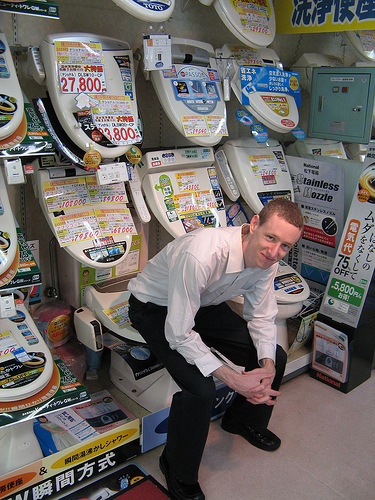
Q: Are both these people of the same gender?
A: No, they are both male and female.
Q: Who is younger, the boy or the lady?
A: The boy is younger than the lady.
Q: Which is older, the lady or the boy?
A: The lady is older than the boy.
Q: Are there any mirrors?
A: No, there are no mirrors.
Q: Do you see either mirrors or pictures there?
A: No, there are no mirrors or pictures.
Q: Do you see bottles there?
A: No, there are no bottles.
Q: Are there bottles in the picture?
A: No, there are no bottles.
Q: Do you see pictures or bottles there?
A: No, there are no bottles or pictures.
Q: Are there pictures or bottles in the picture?
A: No, there are no bottles or pictures.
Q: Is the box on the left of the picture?
A: Yes, the box is on the left of the image.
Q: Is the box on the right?
A: No, the box is on the left of the image.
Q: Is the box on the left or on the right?
A: The box is on the left of the image.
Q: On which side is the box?
A: The box is on the left of the image.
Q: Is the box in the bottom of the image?
A: Yes, the box is in the bottom of the image.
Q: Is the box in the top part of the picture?
A: No, the box is in the bottom of the image.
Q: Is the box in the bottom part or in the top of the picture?
A: The box is in the bottom of the image.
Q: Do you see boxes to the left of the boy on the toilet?
A: Yes, there is a box to the left of the boy.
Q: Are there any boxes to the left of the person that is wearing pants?
A: Yes, there is a box to the left of the boy.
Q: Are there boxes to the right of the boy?
A: No, the box is to the left of the boy.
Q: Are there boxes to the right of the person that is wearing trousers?
A: No, the box is to the left of the boy.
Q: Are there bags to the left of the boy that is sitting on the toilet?
A: No, there is a box to the left of the boy.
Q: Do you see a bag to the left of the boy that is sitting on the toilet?
A: No, there is a box to the left of the boy.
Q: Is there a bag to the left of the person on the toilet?
A: No, there is a box to the left of the boy.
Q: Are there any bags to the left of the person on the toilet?
A: No, there is a box to the left of the boy.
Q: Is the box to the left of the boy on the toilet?
A: Yes, the box is to the left of the boy.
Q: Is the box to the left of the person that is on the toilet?
A: Yes, the box is to the left of the boy.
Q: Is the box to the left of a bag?
A: No, the box is to the left of the boy.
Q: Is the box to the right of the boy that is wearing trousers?
A: No, the box is to the left of the boy.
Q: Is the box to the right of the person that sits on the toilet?
A: No, the box is to the left of the boy.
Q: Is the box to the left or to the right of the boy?
A: The box is to the left of the boy.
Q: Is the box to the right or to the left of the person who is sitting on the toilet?
A: The box is to the left of the boy.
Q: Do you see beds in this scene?
A: No, there are no beds.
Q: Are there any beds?
A: No, there are no beds.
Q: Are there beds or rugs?
A: No, there are no beds or rugs.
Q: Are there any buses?
A: No, there are no buses.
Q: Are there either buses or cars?
A: No, there are no buses or cars.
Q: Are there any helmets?
A: No, there are no helmets.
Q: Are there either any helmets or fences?
A: No, there are no helmets or fences.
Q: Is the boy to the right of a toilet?
A: Yes, the boy is to the right of a toilet.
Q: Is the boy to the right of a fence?
A: No, the boy is to the right of a toilet.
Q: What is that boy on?
A: The boy is on the toilet.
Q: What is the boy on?
A: The boy is on the toilet.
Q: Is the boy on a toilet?
A: Yes, the boy is on a toilet.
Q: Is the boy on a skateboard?
A: No, the boy is on a toilet.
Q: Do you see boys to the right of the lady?
A: Yes, there is a boy to the right of the lady.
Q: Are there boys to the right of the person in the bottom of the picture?
A: Yes, there is a boy to the right of the lady.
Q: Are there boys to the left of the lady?
A: No, the boy is to the right of the lady.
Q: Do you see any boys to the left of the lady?
A: No, the boy is to the right of the lady.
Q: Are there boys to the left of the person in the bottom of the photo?
A: No, the boy is to the right of the lady.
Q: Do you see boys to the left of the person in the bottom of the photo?
A: No, the boy is to the right of the lady.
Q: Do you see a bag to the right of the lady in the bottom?
A: No, there is a boy to the right of the lady.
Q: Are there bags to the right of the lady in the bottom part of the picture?
A: No, there is a boy to the right of the lady.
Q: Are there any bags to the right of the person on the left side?
A: No, there is a boy to the right of the lady.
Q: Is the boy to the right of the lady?
A: Yes, the boy is to the right of the lady.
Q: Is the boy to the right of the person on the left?
A: Yes, the boy is to the right of the lady.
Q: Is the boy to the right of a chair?
A: No, the boy is to the right of the lady.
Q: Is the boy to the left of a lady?
A: No, the boy is to the right of a lady.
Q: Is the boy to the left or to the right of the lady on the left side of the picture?
A: The boy is to the right of the lady.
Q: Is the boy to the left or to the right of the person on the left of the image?
A: The boy is to the right of the lady.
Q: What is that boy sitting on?
A: The boy is sitting on the toilet.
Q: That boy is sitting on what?
A: The boy is sitting on the toilet.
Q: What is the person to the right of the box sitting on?
A: The boy is sitting on the toilet.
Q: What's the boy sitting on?
A: The boy is sitting on the toilet.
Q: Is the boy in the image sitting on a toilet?
A: Yes, the boy is sitting on a toilet.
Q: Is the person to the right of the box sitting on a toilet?
A: Yes, the boy is sitting on a toilet.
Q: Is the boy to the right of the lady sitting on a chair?
A: No, the boy is sitting on a toilet.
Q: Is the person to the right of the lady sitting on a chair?
A: No, the boy is sitting on a toilet.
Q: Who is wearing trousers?
A: The boy is wearing trousers.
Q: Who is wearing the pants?
A: The boy is wearing trousers.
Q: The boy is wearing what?
A: The boy is wearing trousers.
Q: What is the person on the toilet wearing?
A: The boy is wearing trousers.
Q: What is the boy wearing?
A: The boy is wearing trousers.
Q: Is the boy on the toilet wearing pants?
A: Yes, the boy is wearing pants.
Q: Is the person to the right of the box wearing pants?
A: Yes, the boy is wearing pants.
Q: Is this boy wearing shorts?
A: No, the boy is wearing pants.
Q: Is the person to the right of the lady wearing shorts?
A: No, the boy is wearing pants.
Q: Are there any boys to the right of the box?
A: Yes, there is a boy to the right of the box.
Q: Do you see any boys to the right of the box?
A: Yes, there is a boy to the right of the box.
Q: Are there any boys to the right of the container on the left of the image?
A: Yes, there is a boy to the right of the box.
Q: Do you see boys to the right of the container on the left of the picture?
A: Yes, there is a boy to the right of the box.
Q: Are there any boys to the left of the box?
A: No, the boy is to the right of the box.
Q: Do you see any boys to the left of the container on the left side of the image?
A: No, the boy is to the right of the box.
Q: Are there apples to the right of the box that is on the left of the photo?
A: No, there is a boy to the right of the box.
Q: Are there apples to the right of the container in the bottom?
A: No, there is a boy to the right of the box.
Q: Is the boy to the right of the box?
A: Yes, the boy is to the right of the box.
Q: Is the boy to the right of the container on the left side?
A: Yes, the boy is to the right of the box.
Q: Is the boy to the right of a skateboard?
A: No, the boy is to the right of the box.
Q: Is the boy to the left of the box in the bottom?
A: No, the boy is to the right of the box.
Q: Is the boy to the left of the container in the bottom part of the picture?
A: No, the boy is to the right of the box.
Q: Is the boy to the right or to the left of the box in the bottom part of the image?
A: The boy is to the right of the box.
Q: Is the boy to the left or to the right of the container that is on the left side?
A: The boy is to the right of the box.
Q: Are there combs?
A: No, there are no combs.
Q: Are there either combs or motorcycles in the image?
A: No, there are no combs or motorcycles.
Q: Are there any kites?
A: No, there are no kites.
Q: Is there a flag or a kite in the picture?
A: No, there are no kites or flags.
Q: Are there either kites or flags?
A: No, there are no kites or flags.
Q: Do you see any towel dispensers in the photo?
A: No, there are no towel dispensers.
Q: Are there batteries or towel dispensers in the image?
A: No, there are no towel dispensers or batteries.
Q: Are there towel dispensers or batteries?
A: No, there are no towel dispensers or batteries.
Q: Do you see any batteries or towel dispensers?
A: No, there are no towel dispensers or batteries.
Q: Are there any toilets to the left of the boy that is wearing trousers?
A: Yes, there is a toilet to the left of the boy.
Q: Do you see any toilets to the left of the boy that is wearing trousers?
A: Yes, there is a toilet to the left of the boy.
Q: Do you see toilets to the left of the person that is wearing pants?
A: Yes, there is a toilet to the left of the boy.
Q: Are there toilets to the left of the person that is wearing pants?
A: Yes, there is a toilet to the left of the boy.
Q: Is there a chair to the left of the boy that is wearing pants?
A: No, there is a toilet to the left of the boy.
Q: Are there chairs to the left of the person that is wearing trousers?
A: No, there is a toilet to the left of the boy.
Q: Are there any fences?
A: No, there are no fences.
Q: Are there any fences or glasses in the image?
A: No, there are no fences or glasses.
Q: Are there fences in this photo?
A: No, there are no fences.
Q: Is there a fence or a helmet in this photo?
A: No, there are no fences or helmets.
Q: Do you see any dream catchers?
A: No, there are no dream catchers.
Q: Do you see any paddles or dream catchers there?
A: No, there are no dream catchers or paddles.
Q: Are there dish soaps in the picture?
A: No, there are no dish soaps.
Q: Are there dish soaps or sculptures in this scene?
A: No, there are no dish soaps or sculptures.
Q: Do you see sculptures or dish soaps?
A: No, there are no dish soaps or sculptures.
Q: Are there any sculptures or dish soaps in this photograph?
A: No, there are no dish soaps or sculptures.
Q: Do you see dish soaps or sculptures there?
A: No, there are no dish soaps or sculptures.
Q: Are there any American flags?
A: No, there are no American flags.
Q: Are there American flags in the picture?
A: No, there are no American flags.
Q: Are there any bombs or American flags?
A: No, there are no American flags or bombs.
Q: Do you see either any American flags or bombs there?
A: No, there are no American flags or bombs.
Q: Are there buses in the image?
A: No, there are no buses.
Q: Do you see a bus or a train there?
A: No, there are no buses or trains.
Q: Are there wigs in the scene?
A: No, there are no wigs.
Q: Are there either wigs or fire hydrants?
A: No, there are no wigs or fire hydrants.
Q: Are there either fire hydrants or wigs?
A: No, there are no wigs or fire hydrants.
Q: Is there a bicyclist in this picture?
A: No, there are no cyclists.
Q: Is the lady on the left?
A: Yes, the lady is on the left of the image.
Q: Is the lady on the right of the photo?
A: No, the lady is on the left of the image.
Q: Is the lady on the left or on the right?
A: The lady is on the left of the image.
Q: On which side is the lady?
A: The lady is on the left of the image.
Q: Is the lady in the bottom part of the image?
A: Yes, the lady is in the bottom of the image.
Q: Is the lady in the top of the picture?
A: No, the lady is in the bottom of the image.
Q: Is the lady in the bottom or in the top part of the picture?
A: The lady is in the bottom of the image.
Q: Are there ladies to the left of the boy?
A: Yes, there is a lady to the left of the boy.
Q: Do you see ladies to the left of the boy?
A: Yes, there is a lady to the left of the boy.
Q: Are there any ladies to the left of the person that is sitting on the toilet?
A: Yes, there is a lady to the left of the boy.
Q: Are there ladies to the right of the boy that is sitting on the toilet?
A: No, the lady is to the left of the boy.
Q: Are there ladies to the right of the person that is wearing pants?
A: No, the lady is to the left of the boy.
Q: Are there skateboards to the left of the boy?
A: No, there is a lady to the left of the boy.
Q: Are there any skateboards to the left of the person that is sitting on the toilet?
A: No, there is a lady to the left of the boy.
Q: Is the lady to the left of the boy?
A: Yes, the lady is to the left of the boy.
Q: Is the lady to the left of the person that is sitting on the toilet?
A: Yes, the lady is to the left of the boy.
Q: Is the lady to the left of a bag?
A: No, the lady is to the left of the boy.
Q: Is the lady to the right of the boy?
A: No, the lady is to the left of the boy.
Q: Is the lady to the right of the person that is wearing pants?
A: No, the lady is to the left of the boy.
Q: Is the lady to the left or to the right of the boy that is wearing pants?
A: The lady is to the left of the boy.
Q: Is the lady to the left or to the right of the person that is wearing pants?
A: The lady is to the left of the boy.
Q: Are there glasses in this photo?
A: No, there are no glasses.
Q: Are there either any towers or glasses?
A: No, there are no glasses or towers.